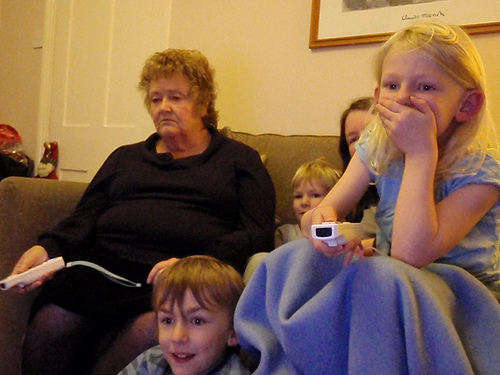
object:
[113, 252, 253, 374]
boy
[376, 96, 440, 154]
hand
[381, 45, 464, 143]
face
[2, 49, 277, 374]
woman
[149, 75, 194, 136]
face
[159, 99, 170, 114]
nose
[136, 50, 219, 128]
hair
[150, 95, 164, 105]
right eye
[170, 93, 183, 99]
left eye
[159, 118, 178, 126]
mouth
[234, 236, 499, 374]
blanket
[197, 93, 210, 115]
ear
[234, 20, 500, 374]
girl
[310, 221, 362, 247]
wiimote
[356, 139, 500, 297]
dress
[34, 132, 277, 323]
clothes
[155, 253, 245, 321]
hair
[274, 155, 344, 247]
boy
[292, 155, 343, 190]
hair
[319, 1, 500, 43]
picture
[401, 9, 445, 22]
signature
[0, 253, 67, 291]
wiimote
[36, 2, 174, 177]
door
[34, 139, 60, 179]
puppet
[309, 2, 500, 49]
frame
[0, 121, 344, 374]
couch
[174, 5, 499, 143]
wall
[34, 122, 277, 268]
sweater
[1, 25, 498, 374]
family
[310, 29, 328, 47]
corner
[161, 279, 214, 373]
face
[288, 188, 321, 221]
face